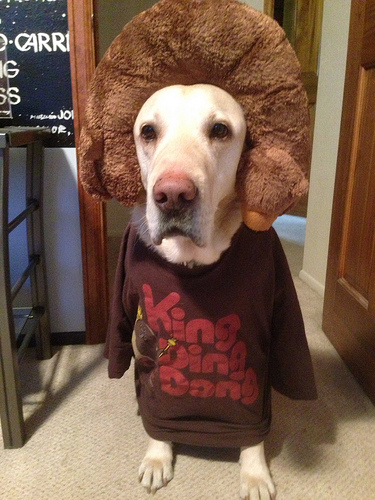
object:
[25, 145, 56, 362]
legs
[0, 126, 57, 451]
table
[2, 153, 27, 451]
legs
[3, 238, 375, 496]
carpet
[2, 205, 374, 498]
floor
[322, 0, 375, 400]
door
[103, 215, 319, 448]
shirt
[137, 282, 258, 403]
writing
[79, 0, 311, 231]
object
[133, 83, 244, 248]
head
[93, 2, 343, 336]
doorway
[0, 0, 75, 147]
sign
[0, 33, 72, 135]
writing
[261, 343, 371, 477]
shadow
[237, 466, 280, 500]
paws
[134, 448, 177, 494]
paws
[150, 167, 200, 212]
nose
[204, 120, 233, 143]
eyes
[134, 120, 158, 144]
eyes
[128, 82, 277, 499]
creature